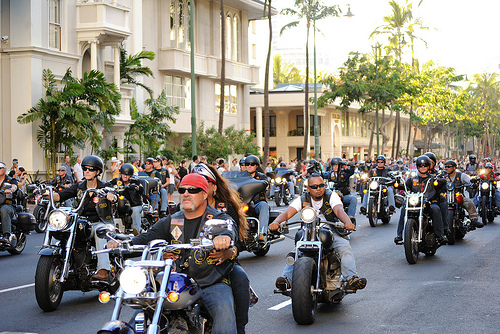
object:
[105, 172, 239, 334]
person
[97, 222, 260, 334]
motorcycle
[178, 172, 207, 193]
bandana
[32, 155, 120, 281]
person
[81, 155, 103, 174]
helmet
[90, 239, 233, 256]
handle bars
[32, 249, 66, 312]
wheel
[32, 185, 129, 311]
motorcycle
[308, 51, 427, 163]
tree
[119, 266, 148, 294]
headlight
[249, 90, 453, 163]
building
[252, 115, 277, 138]
window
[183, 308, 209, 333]
gas tank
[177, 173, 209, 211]
head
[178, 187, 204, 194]
sunglasses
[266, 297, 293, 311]
line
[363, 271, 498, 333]
road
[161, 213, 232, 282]
vest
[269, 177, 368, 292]
person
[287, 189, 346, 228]
shirt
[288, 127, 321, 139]
balcony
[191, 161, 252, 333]
person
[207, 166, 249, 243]
hair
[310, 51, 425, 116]
leaves